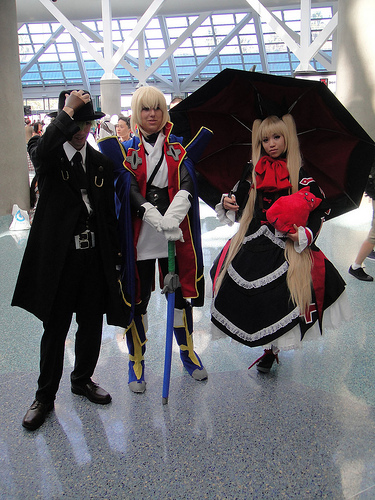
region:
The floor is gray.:
[189, 421, 323, 495]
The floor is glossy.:
[179, 421, 299, 494]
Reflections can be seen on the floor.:
[60, 414, 184, 488]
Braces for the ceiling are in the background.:
[17, 0, 334, 64]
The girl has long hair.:
[225, 107, 339, 327]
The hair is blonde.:
[218, 109, 325, 319]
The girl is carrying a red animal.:
[253, 178, 328, 247]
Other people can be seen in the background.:
[19, 95, 49, 141]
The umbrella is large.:
[161, 66, 373, 232]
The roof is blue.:
[25, 61, 186, 81]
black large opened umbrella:
[189, 79, 291, 109]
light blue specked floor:
[178, 415, 268, 467]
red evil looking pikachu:
[273, 174, 318, 237]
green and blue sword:
[152, 223, 185, 356]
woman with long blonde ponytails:
[241, 113, 309, 257]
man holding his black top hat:
[56, 89, 87, 117]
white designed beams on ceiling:
[71, 21, 274, 61]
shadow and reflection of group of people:
[118, 370, 299, 477]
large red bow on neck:
[252, 161, 309, 200]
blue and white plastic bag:
[12, 205, 40, 235]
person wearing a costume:
[109, 84, 209, 391]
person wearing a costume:
[0, 82, 135, 432]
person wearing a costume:
[203, 106, 351, 376]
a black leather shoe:
[15, 386, 56, 437]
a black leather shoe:
[69, 374, 111, 407]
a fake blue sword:
[152, 221, 188, 407]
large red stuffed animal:
[263, 184, 325, 236]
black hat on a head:
[44, 86, 107, 125]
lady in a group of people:
[111, 115, 135, 142]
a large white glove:
[158, 187, 194, 235]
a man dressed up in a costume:
[15, 84, 123, 437]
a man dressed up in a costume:
[105, 85, 210, 396]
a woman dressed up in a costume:
[165, 67, 374, 380]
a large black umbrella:
[165, 65, 373, 227]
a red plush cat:
[264, 183, 322, 234]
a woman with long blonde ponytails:
[210, 111, 315, 311]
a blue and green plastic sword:
[156, 233, 181, 407]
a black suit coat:
[12, 115, 126, 322]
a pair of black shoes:
[19, 373, 113, 433]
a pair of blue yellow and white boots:
[116, 312, 209, 395]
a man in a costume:
[28, 62, 124, 458]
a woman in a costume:
[117, 77, 204, 480]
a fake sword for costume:
[136, 230, 213, 406]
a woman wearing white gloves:
[155, 169, 203, 238]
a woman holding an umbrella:
[182, 57, 370, 286]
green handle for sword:
[160, 235, 194, 278]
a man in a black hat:
[35, 66, 109, 172]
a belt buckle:
[61, 206, 100, 259]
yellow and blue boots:
[110, 304, 161, 392]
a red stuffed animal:
[252, 163, 332, 250]